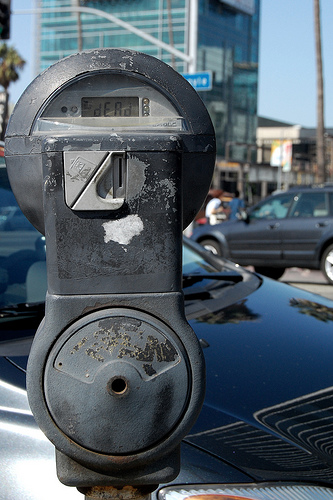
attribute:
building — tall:
[31, 0, 263, 164]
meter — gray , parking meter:
[3, 48, 216, 498]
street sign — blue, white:
[180, 71, 216, 90]